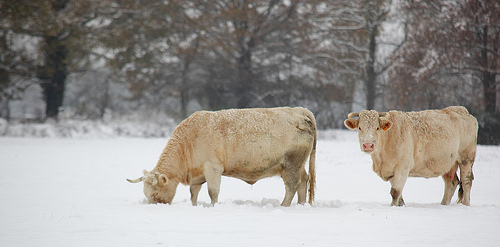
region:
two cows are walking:
[110, 80, 488, 232]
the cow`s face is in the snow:
[97, 145, 192, 210]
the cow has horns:
[117, 162, 164, 192]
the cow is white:
[119, 98, 325, 205]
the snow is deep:
[121, 178, 348, 228]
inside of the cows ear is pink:
[374, 119, 402, 136]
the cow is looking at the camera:
[333, 102, 410, 158]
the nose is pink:
[353, 139, 377, 153]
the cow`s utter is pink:
[419, 152, 460, 189]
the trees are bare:
[187, 2, 367, 109]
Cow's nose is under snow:
[138, 165, 178, 206]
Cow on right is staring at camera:
[345, 106, 389, 153]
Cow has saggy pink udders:
[438, 168, 458, 185]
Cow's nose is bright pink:
[361, 139, 376, 154]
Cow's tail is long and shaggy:
[308, 154, 317, 206]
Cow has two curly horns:
[344, 111, 391, 121]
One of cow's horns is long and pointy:
[121, 178, 144, 183]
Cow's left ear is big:
[379, 115, 393, 132]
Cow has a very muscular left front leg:
[202, 156, 224, 203]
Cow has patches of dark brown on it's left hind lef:
[459, 151, 474, 204]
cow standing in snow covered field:
[336, 85, 486, 217]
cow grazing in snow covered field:
[96, 83, 333, 221]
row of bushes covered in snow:
[0, 108, 161, 135]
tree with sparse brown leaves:
[167, 0, 277, 64]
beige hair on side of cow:
[232, 122, 277, 147]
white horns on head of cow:
[340, 100, 395, 118]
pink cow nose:
[358, 135, 377, 152]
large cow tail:
[303, 113, 326, 208]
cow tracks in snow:
[229, 193, 277, 213]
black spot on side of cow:
[444, 143, 461, 165]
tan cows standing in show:
[125, 100, 480, 212]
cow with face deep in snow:
[120, 165, 175, 210]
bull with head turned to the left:
[342, 96, 402, 178]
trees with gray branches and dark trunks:
[22, 6, 483, 126]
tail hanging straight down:
[295, 100, 315, 205]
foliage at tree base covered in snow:
[2, 105, 152, 140]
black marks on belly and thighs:
[222, 150, 307, 187]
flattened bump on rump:
[440, 100, 475, 132]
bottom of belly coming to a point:
[222, 165, 272, 185]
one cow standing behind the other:
[118, 101, 481, 208]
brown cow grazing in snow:
[130, 145, 190, 215]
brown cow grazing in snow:
[111, 118, 231, 228]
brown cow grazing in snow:
[117, 97, 327, 234]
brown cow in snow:
[339, 101, 486, 213]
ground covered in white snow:
[21, 147, 87, 185]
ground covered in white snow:
[21, 183, 101, 222]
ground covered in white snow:
[236, 215, 341, 238]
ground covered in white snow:
[334, 178, 367, 228]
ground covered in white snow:
[377, 211, 453, 239]